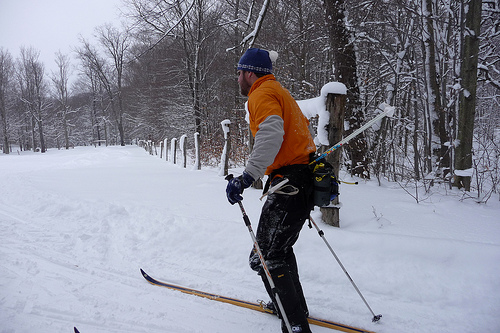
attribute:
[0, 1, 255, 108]
sky — cloudless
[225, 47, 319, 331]
man — skiing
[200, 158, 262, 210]
gloves — blue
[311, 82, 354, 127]
post — wooden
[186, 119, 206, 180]
post — wooden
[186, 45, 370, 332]
skier — skiing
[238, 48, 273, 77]
hat — blue, beanie, white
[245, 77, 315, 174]
sweater — orange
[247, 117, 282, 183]
sleeve — gray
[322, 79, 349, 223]
post — wooden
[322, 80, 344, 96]
snow — capped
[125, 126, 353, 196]
fence — wooden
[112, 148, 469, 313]
snow — white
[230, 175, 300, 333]
ski pole — black, white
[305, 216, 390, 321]
ski pole — black, white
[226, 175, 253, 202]
glove — black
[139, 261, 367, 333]
ski — black, white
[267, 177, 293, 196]
handle — white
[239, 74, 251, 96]
beard — brown